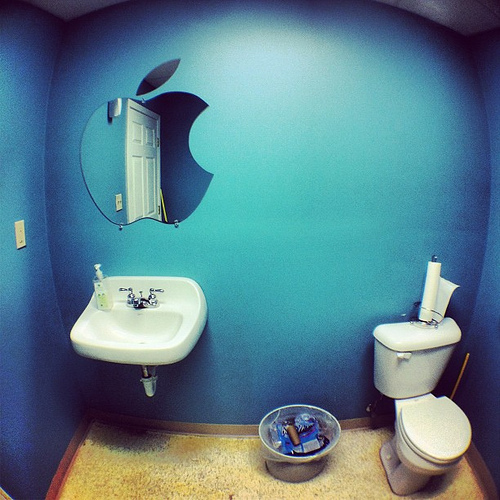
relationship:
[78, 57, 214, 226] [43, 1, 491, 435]
mirror hanging on wall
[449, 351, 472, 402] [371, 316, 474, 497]
plunger handle behind toilet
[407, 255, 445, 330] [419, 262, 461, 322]
paper towel holder with roll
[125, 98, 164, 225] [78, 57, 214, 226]
door reflection showing in mirror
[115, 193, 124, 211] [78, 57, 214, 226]
light switch reflected in mirror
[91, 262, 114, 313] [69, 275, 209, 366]
hand soap on side of sink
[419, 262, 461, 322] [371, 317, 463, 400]
roll on top of tank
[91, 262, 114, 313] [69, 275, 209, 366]
hand soap sitting next to sink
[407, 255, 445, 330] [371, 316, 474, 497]
paper towel holder on top of toilet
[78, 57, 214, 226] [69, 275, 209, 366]
mirror above sink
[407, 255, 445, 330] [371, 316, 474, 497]
paper towel holder on back of toilet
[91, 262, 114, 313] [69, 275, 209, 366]
hand soap on top of sink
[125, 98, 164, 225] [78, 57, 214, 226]
door reflection reflected in mirror